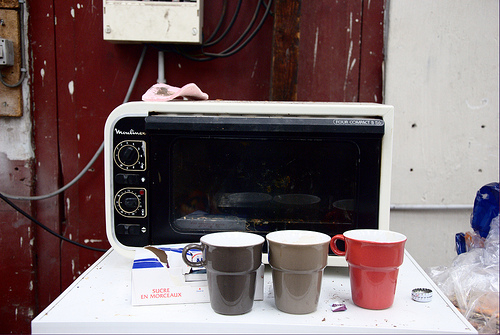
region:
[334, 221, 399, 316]
red mug on dryer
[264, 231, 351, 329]
light brown mug on dryer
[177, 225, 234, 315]
dark brown mug on dryer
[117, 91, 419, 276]
black and white oven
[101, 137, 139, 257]
two dials on oven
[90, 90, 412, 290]
oven sits on dryer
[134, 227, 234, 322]
white box near mugs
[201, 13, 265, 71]
black cords on wall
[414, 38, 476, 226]
white wall behind oven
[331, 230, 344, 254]
a handle on the cup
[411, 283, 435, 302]
a cap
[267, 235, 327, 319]
a brown mug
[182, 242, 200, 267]
a handle on the brown mug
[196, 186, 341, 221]
reflection on the microwave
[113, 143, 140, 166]
knobs on the microwave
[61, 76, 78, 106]
white paint on the door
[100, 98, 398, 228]
a microwave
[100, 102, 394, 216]
the microwave is black and white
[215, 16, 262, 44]
the cords are black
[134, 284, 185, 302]
French wording on package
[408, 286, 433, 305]
Two bottle caps on table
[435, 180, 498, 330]
Plastic waste in front of white wall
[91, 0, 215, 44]
Electrical box on wooden wall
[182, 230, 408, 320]
Three coffee cups on table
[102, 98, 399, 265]
Black and white toaster oven on table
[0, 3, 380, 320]
Red wooden wall with chipped paint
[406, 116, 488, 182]
Four holes drilled into wall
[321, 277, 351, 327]
Spilled granules on white table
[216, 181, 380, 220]
Reflection of coffee cups in toaster oven